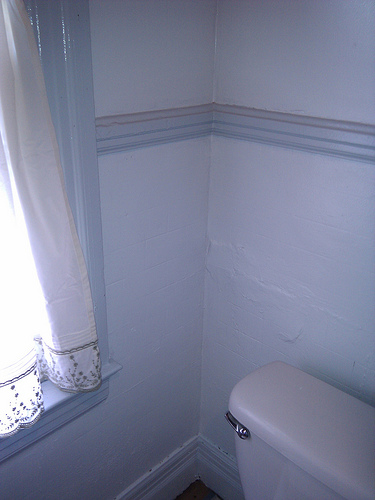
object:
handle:
[225, 413, 252, 440]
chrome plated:
[234, 425, 241, 433]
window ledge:
[0, 357, 123, 462]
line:
[213, 120, 375, 164]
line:
[96, 120, 213, 154]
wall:
[198, 1, 375, 499]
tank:
[225, 360, 375, 499]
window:
[0, 0, 96, 398]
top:
[226, 359, 374, 498]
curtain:
[0, 0, 104, 437]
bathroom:
[0, 0, 373, 498]